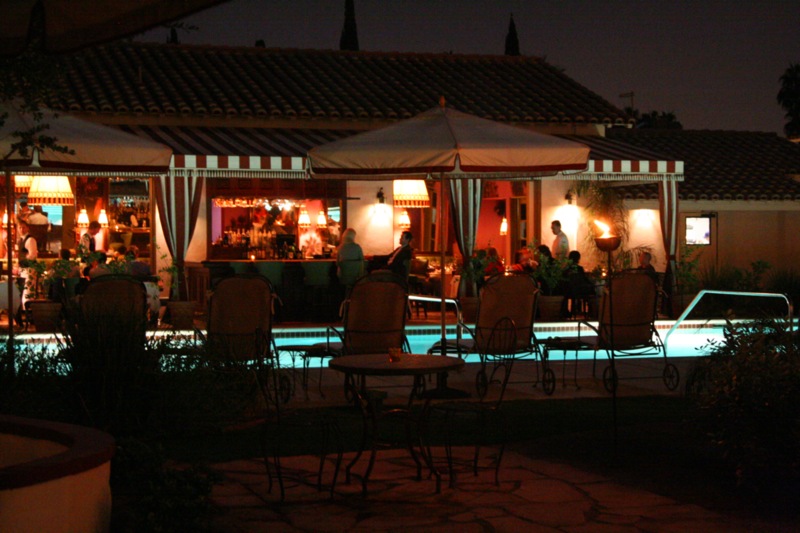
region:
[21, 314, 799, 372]
the pool is blue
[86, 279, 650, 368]
the chairs are by the pool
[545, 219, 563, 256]
the man is standing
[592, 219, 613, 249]
the fire is on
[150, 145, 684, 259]
the awning has stripes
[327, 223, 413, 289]
the people are sitting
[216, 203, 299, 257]
the bar is stocked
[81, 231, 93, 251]
the waiter wears white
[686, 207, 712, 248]
the window is open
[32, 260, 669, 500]
five lounge chairs in a row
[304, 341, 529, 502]
an empty dining table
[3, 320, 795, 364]
a lit up outdoor pool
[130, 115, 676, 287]
red and white striped canopy of a restaurant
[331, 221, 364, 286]
a person sitting on a chair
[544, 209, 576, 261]
a man standing up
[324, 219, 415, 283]
two people sitting on chairs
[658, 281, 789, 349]
metal railing of a pool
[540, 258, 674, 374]
an empty lounge chair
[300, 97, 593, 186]
umbrella on top of pole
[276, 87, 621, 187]
umbrella is tan in color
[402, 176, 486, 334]
pole with umbrella on top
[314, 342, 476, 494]
table on the deck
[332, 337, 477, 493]
table is brown in color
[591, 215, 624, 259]
torch on top of pole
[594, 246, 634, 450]
pole with torch on top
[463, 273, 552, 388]
chair on top of deck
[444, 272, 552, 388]
chair is brown in color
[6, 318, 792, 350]
swimming pool is blue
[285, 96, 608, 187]
a brown umbrella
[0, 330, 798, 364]
an in ground swimming pool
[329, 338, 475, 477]
a small patio table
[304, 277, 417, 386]
A chair that is outside.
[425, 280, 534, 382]
A chair that is outside.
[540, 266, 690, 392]
A chair that is outside.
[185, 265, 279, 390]
A chair that is outside.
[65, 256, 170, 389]
A chair that is outside.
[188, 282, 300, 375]
A chair that you sit in.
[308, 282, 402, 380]
A chair that you sit in.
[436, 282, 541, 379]
A chair that you sit in.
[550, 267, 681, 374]
A chair that you sit in.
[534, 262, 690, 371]
beach chair beside pool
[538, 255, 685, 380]
beach chair beside pool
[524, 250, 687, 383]
beach chair beside pool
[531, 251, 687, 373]
beach chair beside pool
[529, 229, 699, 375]
beach chair beside pool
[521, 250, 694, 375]
beach chair beside pool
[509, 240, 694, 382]
beach chair beside pool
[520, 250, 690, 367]
beach chair beside pool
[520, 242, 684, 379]
beach chair beside pool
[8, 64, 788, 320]
a large house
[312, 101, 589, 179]
a large white umbrella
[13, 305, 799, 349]
a swimming pool in front of the house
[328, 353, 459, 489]
a small round table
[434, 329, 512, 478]
a chair in front of the table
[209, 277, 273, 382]
a large chair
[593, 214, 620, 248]
a flame on the torch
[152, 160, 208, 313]
a brown and blue curtain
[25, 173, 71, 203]
a light hanging from the ceiling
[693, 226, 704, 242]
glass window on the building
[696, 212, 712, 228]
glass window on the building